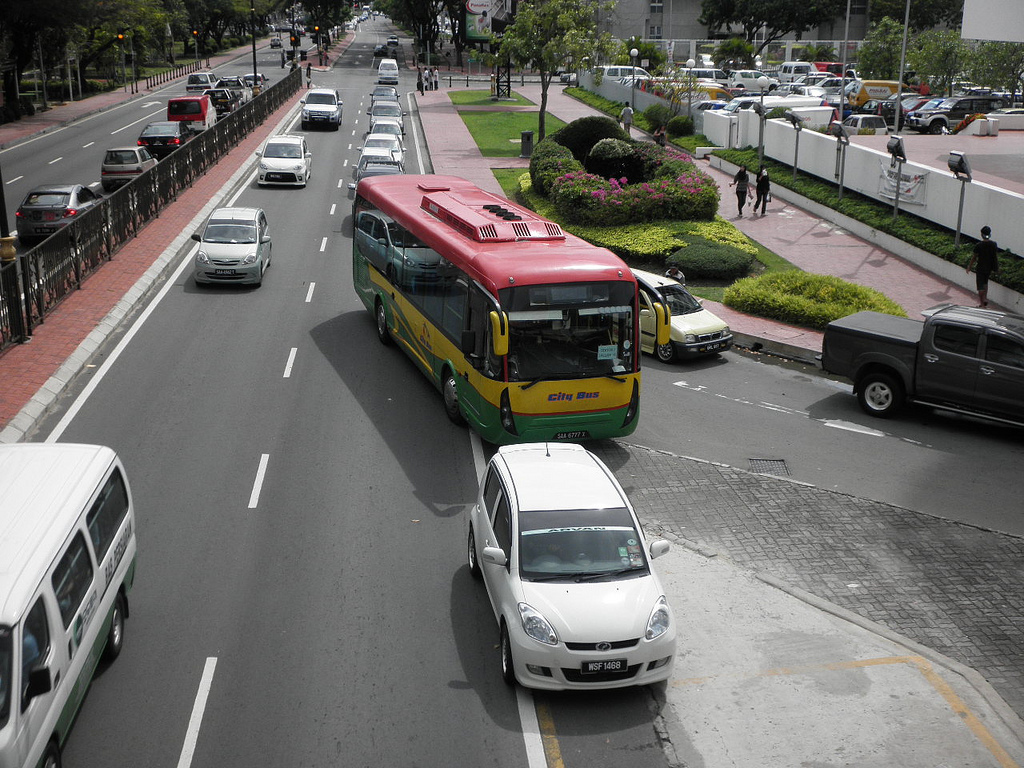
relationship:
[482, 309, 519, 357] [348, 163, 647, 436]
mirrors are on bus